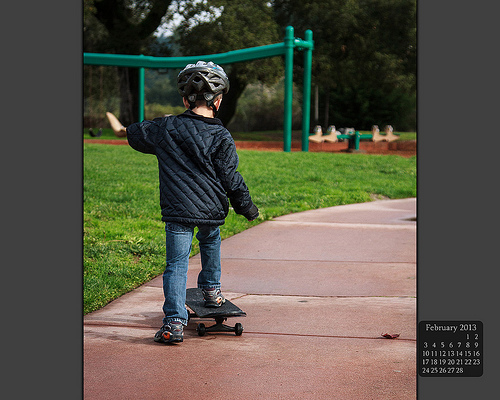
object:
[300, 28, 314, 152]
pole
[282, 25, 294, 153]
pole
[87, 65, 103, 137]
swing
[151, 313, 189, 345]
foot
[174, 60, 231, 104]
helmet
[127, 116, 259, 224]
jacket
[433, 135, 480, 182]
ground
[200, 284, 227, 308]
shoe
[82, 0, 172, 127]
tree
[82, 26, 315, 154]
swing set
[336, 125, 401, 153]
teeter totters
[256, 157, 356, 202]
grass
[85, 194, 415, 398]
wet sidewalk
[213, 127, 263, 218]
hand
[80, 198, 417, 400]
pavement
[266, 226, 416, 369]
red pavement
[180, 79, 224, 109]
head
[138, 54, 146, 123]
pole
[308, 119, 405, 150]
see saw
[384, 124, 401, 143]
seat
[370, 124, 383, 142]
seat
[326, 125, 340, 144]
seat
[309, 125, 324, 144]
seat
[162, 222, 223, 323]
jeans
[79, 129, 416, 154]
playground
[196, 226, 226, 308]
leg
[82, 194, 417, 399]
sidewalk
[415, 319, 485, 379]
calendar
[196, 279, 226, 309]
foot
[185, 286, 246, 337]
skateboard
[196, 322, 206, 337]
wheel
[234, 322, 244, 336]
wheel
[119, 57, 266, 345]
boy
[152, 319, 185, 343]
shoe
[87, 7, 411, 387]
park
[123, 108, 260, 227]
coat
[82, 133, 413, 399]
ground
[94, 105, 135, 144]
hand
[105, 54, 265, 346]
rider